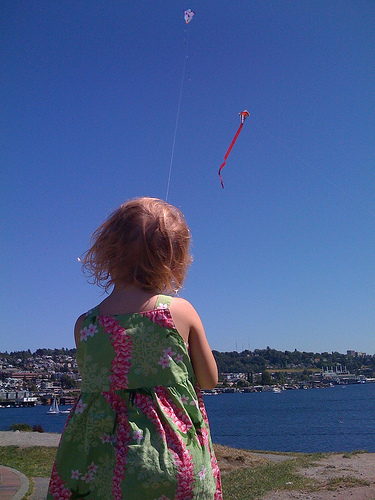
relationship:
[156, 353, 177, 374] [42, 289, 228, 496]
flower on dress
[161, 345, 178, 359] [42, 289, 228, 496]
flower on dress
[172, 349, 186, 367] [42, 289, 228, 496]
flower on dress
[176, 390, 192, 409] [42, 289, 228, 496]
flower on dress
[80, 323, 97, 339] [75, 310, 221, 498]
flower are on dress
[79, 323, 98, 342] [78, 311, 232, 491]
flower on dress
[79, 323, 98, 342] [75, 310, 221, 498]
flower on dress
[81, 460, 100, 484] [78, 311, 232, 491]
flower on dress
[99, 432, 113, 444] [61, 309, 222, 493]
flower on dress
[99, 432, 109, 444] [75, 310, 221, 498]
flower on dress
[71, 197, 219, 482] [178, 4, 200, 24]
child flying a kite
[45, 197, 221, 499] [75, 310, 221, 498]
child wearing a dress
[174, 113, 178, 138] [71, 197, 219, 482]
string in front of child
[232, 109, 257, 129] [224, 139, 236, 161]
kite has a red tail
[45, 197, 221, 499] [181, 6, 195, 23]
child flying a kite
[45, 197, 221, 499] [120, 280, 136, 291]
child has a neck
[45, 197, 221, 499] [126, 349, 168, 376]
child has a back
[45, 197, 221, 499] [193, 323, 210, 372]
child has an arm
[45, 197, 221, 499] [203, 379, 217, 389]
child has an elbow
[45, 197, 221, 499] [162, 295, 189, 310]
child has a shoulder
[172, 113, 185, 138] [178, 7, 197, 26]
string attached to kite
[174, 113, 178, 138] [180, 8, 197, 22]
string attached to kite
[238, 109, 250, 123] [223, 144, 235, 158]
kite has a red tail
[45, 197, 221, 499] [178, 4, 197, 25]
child flying kite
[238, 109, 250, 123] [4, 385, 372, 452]
kite flying over water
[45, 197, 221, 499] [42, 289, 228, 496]
child wearing dress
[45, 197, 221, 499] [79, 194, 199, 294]
child has hair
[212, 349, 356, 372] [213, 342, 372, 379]
trees on mountain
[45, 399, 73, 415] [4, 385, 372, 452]
boat on water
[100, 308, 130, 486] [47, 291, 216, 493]
flowers on dress